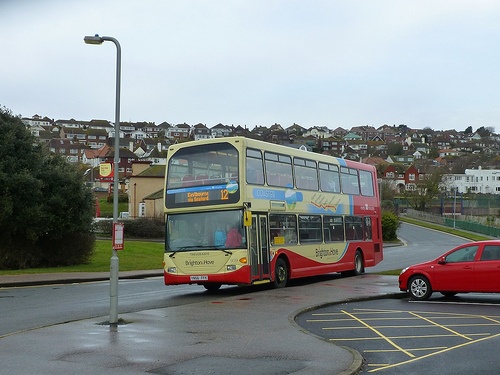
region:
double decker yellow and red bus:
[157, 130, 387, 290]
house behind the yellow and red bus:
[403, 165, 430, 195]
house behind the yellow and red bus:
[131, 140, 151, 162]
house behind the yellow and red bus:
[80, 141, 105, 163]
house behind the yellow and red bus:
[162, 124, 189, 138]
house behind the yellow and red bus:
[343, 128, 360, 140]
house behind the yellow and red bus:
[306, 125, 331, 140]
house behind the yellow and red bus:
[25, 113, 54, 128]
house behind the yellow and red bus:
[60, 125, 90, 142]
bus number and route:
[174, 185, 229, 204]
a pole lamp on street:
[74, 32, 127, 327]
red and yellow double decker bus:
[166, 133, 387, 283]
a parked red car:
[401, 227, 498, 304]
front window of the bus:
[169, 216, 246, 248]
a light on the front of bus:
[224, 265, 236, 272]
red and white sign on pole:
[113, 220, 124, 250]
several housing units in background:
[374, 125, 486, 185]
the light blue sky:
[131, 0, 455, 115]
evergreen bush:
[0, 106, 100, 271]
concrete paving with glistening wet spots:
[3, 273, 414, 372]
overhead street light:
[81, 32, 123, 327]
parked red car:
[395, 237, 498, 302]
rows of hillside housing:
[16, 111, 498, 171]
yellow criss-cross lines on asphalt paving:
[291, 288, 498, 373]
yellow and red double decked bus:
[160, 135, 385, 292]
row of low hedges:
[92, 211, 165, 239]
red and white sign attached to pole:
[109, 220, 126, 252]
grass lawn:
[1, 234, 164, 274]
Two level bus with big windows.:
[132, 113, 392, 299]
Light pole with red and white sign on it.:
[62, 16, 134, 331]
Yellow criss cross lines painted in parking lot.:
[280, 248, 496, 374]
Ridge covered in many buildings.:
[12, 102, 498, 206]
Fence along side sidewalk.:
[401, 180, 496, 244]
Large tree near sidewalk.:
[0, 89, 109, 296]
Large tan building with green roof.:
[104, 145, 170, 227]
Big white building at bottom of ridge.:
[412, 133, 499, 214]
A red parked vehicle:
[397, 240, 499, 300]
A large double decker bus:
[162, 135, 382, 290]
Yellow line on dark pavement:
[339, 306, 416, 360]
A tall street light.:
[82, 33, 120, 323]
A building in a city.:
[143, 150, 172, 167]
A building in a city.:
[63, 124, 104, 154]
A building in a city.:
[384, 161, 444, 198]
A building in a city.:
[436, 163, 495, 195]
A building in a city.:
[342, 131, 361, 143]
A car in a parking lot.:
[396, 233, 496, 299]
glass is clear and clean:
[166, 144, 241, 189]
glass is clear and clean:
[247, 149, 264, 160]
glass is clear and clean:
[245, 157, 264, 185]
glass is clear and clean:
[293, 164, 316, 187]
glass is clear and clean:
[320, 169, 340, 196]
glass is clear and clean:
[359, 171, 376, 196]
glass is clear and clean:
[446, 245, 478, 262]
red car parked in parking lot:
[397, 238, 499, 300]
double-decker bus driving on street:
[161, 135, 385, 290]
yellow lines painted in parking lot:
[308, 311, 498, 373]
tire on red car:
[406, 275, 431, 301]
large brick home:
[378, 162, 434, 199]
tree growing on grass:
[1, 106, 96, 266]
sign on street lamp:
[111, 220, 125, 249]